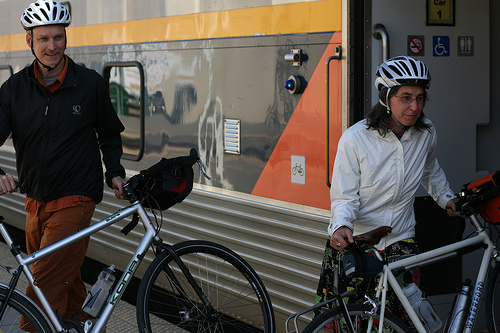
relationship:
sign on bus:
[407, 34, 423, 56] [1, 0, 498, 330]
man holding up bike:
[2, 1, 131, 331] [2, 159, 289, 330]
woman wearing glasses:
[326, 55, 463, 333] [371, 85, 435, 114]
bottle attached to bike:
[81, 263, 120, 318] [2, 159, 289, 330]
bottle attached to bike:
[400, 282, 445, 333] [296, 190, 494, 332]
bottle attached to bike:
[438, 281, 466, 331] [296, 190, 494, 332]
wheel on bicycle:
[134, 237, 275, 331] [32, 162, 265, 310]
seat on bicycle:
[345, 225, 390, 246] [285, 176, 490, 331]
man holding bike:
[2, 1, 131, 331] [296, 190, 494, 332]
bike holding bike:
[296, 190, 494, 332] [2, 159, 289, 330]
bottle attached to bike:
[423, 172, 477, 264] [310, 73, 497, 300]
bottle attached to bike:
[80, 264, 117, 319] [0, 148, 275, 331]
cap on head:
[374, 55, 431, 91] [382, 85, 427, 133]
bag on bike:
[123, 155, 200, 211] [0, 178, 277, 329]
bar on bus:
[320, 52, 331, 181] [94, 10, 326, 215]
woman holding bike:
[333, 47, 444, 269] [288, 201, 493, 321]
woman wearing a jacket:
[326, 55, 463, 333] [323, 106, 460, 246]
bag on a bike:
[123, 147, 203, 211] [2, 159, 289, 330]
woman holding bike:
[326, 55, 463, 333] [282, 172, 498, 329]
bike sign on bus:
[287, 155, 307, 187] [1, 0, 498, 330]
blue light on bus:
[283, 76, 300, 90] [1, 0, 498, 330]